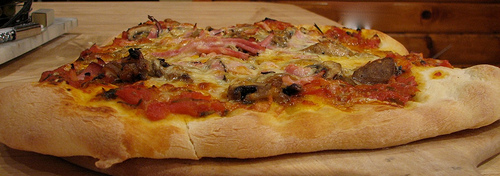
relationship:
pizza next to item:
[4, 15, 496, 167] [1, 10, 76, 55]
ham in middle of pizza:
[233, 36, 266, 54] [4, 15, 496, 167]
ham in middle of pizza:
[209, 43, 244, 60] [4, 15, 496, 167]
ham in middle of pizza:
[192, 31, 244, 45] [4, 15, 496, 167]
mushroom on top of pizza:
[349, 53, 400, 89] [4, 15, 496, 167]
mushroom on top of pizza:
[231, 65, 296, 105] [4, 15, 496, 167]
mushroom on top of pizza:
[316, 57, 346, 82] [4, 15, 496, 167]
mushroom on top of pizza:
[126, 20, 162, 42] [4, 15, 496, 167]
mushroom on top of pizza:
[256, 26, 297, 53] [4, 15, 496, 167]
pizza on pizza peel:
[4, 15, 496, 167] [2, 0, 487, 174]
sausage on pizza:
[115, 33, 157, 75] [21, 0, 480, 144]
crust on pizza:
[0, 64, 499, 169] [4, 15, 496, 167]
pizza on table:
[4, 15, 496, 167] [5, 1, 350, 82]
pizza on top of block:
[4, 15, 496, 167] [0, 122, 499, 174]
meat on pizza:
[355, 53, 395, 85] [4, 15, 496, 167]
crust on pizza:
[13, 82, 499, 164] [4, 15, 496, 167]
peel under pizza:
[59, 128, 499, 173] [4, 15, 496, 167]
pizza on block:
[4, 15, 496, 146] [4, 30, 496, 174]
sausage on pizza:
[255, 68, 292, 106] [89, 14, 480, 161]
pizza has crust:
[4, 15, 496, 167] [0, 64, 499, 169]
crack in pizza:
[175, 115, 209, 167] [4, 15, 496, 167]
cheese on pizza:
[63, 19, 428, 111] [4, 15, 496, 167]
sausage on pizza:
[351, 56, 398, 83] [4, 15, 496, 167]